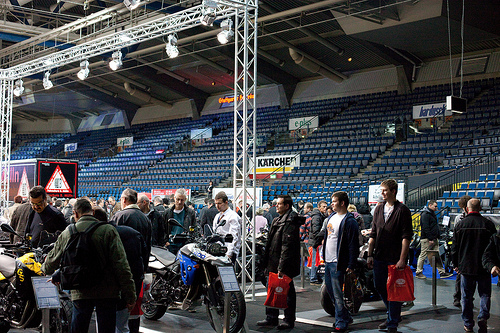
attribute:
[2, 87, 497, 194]
terraces — blue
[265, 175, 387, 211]
stand — metallic, metal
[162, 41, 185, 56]
light — strong, down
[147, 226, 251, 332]
bike — nice, blue, parked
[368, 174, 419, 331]
man — walking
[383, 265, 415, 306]
bag — red, plastic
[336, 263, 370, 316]
bag — brown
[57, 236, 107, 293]
backpack — dark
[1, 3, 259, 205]
structure — metal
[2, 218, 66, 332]
motorcycle — parked, yellow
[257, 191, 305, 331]
man — smiling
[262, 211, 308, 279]
jacket — white, dark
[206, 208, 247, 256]
jacket — white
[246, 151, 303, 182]
sign — large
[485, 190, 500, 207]
seat — blue, empty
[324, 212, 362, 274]
sweater — dark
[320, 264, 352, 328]
jeans — blue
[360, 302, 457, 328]
shadow — cast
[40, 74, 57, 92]
light — off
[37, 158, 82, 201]
sign — black, red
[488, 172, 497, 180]
seat — blue